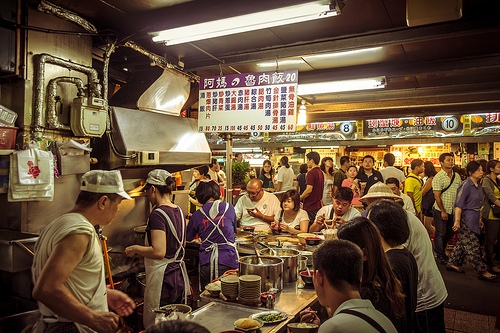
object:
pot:
[235, 256, 283, 298]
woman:
[269, 187, 310, 237]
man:
[234, 178, 280, 231]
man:
[308, 186, 362, 234]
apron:
[142, 206, 188, 330]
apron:
[68, 219, 111, 333]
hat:
[78, 169, 135, 201]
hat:
[136, 169, 175, 192]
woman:
[185, 176, 242, 283]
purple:
[191, 202, 239, 269]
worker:
[121, 166, 195, 322]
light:
[146, 4, 334, 43]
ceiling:
[49, 0, 500, 69]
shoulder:
[315, 309, 351, 332]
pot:
[259, 245, 298, 289]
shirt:
[402, 171, 427, 214]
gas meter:
[70, 97, 108, 138]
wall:
[26, 26, 115, 162]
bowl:
[299, 269, 313, 285]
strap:
[438, 169, 457, 195]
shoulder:
[446, 169, 463, 187]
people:
[446, 160, 497, 281]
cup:
[260, 292, 277, 308]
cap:
[204, 284, 221, 297]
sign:
[195, 68, 296, 134]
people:
[311, 240, 398, 332]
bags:
[15, 144, 49, 185]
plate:
[250, 308, 290, 326]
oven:
[23, 0, 91, 237]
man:
[30, 169, 133, 333]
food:
[157, 303, 187, 315]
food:
[254, 312, 290, 323]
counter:
[185, 227, 320, 333]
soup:
[298, 267, 314, 286]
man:
[298, 151, 324, 228]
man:
[430, 152, 463, 265]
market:
[194, 134, 499, 227]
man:
[359, 182, 442, 282]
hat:
[359, 182, 403, 203]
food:
[270, 219, 283, 232]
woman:
[339, 164, 360, 198]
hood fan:
[94, 105, 212, 180]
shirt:
[432, 169, 462, 218]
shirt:
[276, 165, 296, 189]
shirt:
[455, 176, 490, 233]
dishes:
[237, 274, 260, 282]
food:
[245, 206, 257, 211]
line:
[266, 144, 445, 190]